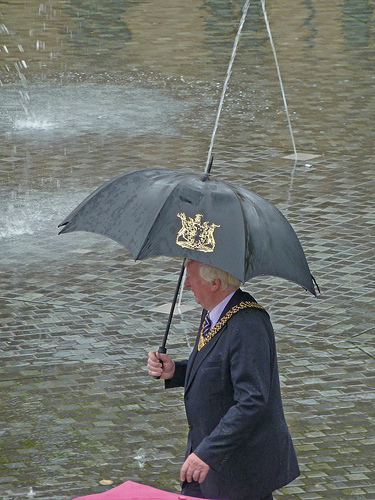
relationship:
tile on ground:
[282, 147, 321, 164] [4, 7, 367, 492]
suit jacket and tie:
[162, 289, 300, 498] [199, 308, 211, 342]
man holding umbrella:
[147, 258, 300, 499] [57, 156, 320, 378]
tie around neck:
[201, 311, 210, 338] [198, 291, 247, 312]